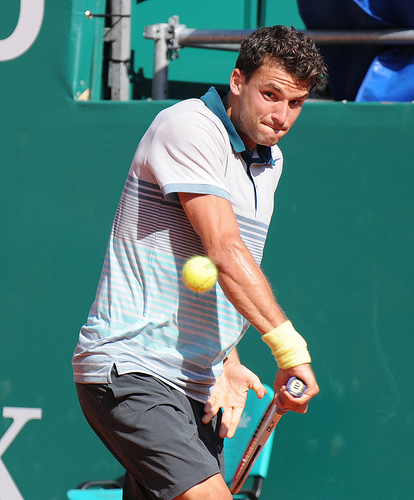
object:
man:
[72, 24, 326, 500]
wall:
[0, 0, 413, 500]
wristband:
[258, 320, 310, 369]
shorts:
[74, 368, 225, 500]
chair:
[65, 380, 275, 500]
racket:
[229, 375, 306, 495]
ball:
[179, 254, 217, 291]